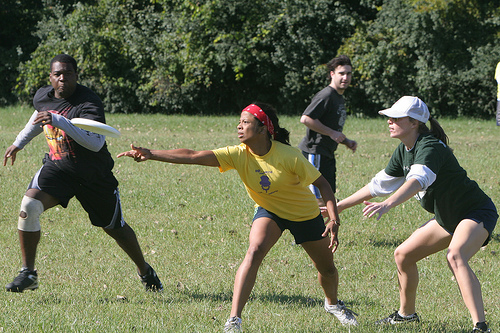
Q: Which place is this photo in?
A: It is at the park.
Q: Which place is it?
A: It is a park.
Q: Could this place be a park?
A: Yes, it is a park.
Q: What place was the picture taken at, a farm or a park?
A: It was taken at a park.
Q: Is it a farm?
A: No, it is a park.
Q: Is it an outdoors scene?
A: Yes, it is outdoors.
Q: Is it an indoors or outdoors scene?
A: It is outdoors.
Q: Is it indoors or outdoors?
A: It is outdoors.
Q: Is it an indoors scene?
A: No, it is outdoors.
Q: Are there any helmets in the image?
A: No, there are no helmets.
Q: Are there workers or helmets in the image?
A: No, there are no helmets or workers.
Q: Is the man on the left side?
A: Yes, the man is on the left of the image.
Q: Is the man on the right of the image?
A: No, the man is on the left of the image.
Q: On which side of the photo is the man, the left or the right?
A: The man is on the left of the image.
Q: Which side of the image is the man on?
A: The man is on the left of the image.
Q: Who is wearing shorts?
A: The man is wearing shorts.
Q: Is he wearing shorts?
A: Yes, the man is wearing shorts.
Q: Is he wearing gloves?
A: No, the man is wearing shorts.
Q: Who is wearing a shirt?
A: The man is wearing a shirt.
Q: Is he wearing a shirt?
A: Yes, the man is wearing a shirt.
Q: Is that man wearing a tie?
A: No, the man is wearing a shirt.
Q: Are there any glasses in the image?
A: No, there are no glasses.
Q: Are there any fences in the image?
A: No, there are no fences.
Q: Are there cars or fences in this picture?
A: No, there are no fences or cars.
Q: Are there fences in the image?
A: No, there are no fences.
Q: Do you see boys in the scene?
A: No, there are no boys.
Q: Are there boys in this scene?
A: No, there are no boys.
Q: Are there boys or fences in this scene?
A: No, there are no boys or fences.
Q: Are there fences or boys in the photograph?
A: No, there are no boys or fences.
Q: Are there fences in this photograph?
A: No, there are no fences.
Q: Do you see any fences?
A: No, there are no fences.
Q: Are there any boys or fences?
A: No, there are no fences or boys.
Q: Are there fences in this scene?
A: No, there are no fences.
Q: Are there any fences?
A: No, there are no fences.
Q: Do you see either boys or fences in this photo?
A: No, there are no boys or fences.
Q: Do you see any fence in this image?
A: No, there are no fences.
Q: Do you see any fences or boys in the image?
A: No, there are no fences or boys.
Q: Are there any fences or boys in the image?
A: No, there are no fences or boys.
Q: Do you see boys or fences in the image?
A: No, there are no fences or boys.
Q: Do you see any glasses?
A: No, there are no glasses.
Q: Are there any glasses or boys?
A: No, there are no glasses or boys.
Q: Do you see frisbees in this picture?
A: Yes, there is a frisbee.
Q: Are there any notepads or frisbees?
A: Yes, there is a frisbee.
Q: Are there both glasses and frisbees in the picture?
A: No, there is a frisbee but no glasses.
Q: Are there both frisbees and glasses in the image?
A: No, there is a frisbee but no glasses.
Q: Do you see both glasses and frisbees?
A: No, there is a frisbee but no glasses.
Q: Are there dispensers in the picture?
A: No, there are no dispensers.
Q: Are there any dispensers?
A: No, there are no dispensers.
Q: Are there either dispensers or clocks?
A: No, there are no dispensers or clocks.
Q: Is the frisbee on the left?
A: Yes, the frisbee is on the left of the image.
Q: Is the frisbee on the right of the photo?
A: No, the frisbee is on the left of the image.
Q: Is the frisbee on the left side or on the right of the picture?
A: The frisbee is on the left of the image.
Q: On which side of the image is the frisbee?
A: The frisbee is on the left of the image.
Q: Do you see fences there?
A: No, there are no fences.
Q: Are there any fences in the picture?
A: No, there are no fences.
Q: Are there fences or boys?
A: No, there are no fences or boys.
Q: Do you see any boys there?
A: No, there are no boys.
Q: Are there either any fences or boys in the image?
A: No, there are no boys or fences.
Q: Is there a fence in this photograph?
A: No, there are no fences.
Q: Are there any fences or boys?
A: No, there are no fences or boys.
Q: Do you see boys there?
A: No, there are no boys.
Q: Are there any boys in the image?
A: No, there are no boys.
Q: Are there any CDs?
A: No, there are no cds.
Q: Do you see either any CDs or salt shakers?
A: No, there are no CDs or salt shakers.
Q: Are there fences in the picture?
A: No, there are no fences.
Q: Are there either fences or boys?
A: No, there are no fences or boys.